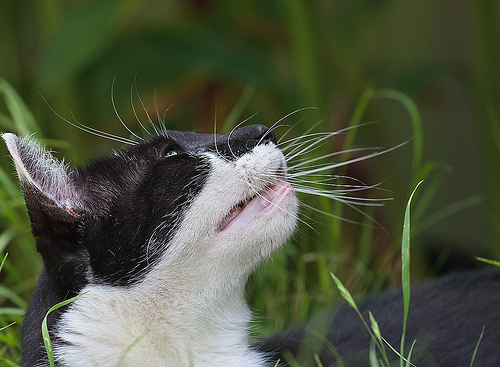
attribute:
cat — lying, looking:
[13, 103, 412, 361]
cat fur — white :
[18, 112, 325, 266]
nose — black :
[232, 112, 287, 154]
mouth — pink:
[218, 162, 290, 236]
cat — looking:
[1, 114, 346, 365]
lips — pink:
[250, 174, 288, 222]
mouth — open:
[210, 162, 321, 244]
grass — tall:
[4, 14, 491, 361]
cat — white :
[82, 134, 309, 338]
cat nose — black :
[231, 125, 273, 151]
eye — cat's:
[158, 140, 182, 162]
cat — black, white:
[0, 118, 497, 363]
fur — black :
[406, 299, 478, 341]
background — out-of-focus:
[26, 12, 366, 105]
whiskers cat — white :
[316, 118, 375, 198]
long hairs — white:
[38, 72, 178, 147]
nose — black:
[224, 110, 280, 151]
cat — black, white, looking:
[7, 108, 301, 365]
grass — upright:
[303, 233, 395, 313]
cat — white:
[23, 62, 410, 336]